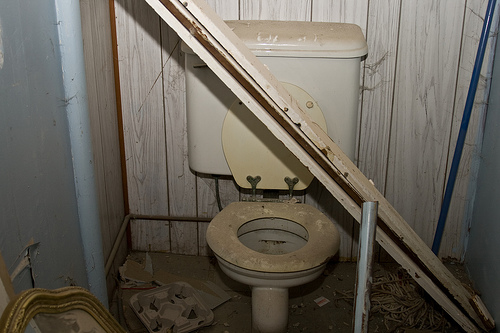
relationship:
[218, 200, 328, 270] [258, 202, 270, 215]
toilet seat that dirty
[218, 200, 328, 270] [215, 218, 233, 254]
toilet seat that yellowish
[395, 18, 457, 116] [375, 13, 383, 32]
wall that white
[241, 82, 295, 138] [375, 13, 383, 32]
wood plank that white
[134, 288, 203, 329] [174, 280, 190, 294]
cup holder that brownish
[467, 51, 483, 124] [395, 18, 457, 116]
pole that on wall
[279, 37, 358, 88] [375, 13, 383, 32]
toilet tank that white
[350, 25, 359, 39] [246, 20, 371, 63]
dust on tank top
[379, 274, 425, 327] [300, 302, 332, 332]
mop laying on floor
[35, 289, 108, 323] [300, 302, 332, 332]
picture frame laying on floor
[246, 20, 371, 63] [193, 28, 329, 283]
tank top of toilet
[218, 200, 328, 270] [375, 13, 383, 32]
toilet seat that white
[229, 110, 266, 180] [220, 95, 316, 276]
toilet lid that up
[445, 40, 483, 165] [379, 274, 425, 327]
blue handle on mop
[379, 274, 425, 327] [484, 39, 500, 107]
mop in corner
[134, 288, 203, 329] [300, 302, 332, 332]
cup holder laying on floor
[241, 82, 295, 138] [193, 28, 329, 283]
wood plank leaning on toilet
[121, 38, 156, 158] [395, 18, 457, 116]
wood paneling on wall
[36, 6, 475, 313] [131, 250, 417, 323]
bathroom that looks odd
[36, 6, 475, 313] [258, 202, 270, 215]
bathroom that dirty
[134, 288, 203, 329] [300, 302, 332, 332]
cup holder thats tan laying on floor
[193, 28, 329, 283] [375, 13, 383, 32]
toilet that white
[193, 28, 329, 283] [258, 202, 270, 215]
toilet that dirty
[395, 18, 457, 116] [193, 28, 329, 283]
wall behind toilet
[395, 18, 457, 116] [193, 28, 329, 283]
wall tan behind toilet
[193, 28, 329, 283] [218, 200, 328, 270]
toilet has a toilet seat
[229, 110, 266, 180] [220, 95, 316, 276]
toilet lid that open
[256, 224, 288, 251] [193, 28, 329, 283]
toilet bowl of a toilet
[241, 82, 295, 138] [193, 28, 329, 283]
wood plank laying on toilet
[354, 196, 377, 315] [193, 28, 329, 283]
metal bar in toilet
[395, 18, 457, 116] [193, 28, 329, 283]
wall in toilet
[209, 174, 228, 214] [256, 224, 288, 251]
water pipe to toilet bowl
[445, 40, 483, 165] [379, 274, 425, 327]
blue handle to mop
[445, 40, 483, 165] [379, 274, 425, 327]
blue handle of mop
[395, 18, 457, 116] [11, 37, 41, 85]
wall that clean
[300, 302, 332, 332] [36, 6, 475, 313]
floor in bathroom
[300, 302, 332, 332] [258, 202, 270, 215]
floor that dirty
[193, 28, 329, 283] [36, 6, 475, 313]
toilet that in bathroom